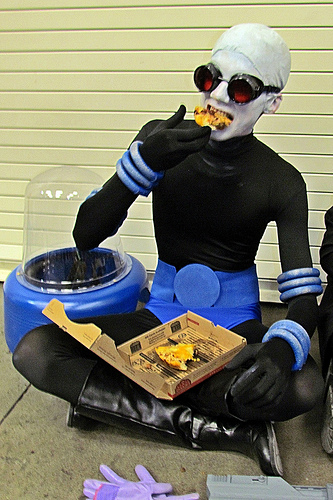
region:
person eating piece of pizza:
[57, 19, 304, 300]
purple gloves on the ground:
[88, 459, 183, 498]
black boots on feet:
[67, 394, 278, 475]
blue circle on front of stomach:
[167, 261, 220, 316]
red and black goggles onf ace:
[193, 56, 267, 100]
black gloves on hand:
[223, 344, 295, 408]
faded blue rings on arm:
[247, 268, 320, 361]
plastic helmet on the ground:
[17, 160, 125, 293]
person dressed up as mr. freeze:
[46, 29, 321, 332]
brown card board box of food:
[99, 315, 236, 392]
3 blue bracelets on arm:
[275, 267, 330, 298]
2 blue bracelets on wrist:
[265, 312, 315, 368]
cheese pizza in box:
[154, 342, 200, 375]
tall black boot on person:
[102, 410, 283, 472]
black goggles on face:
[193, 65, 266, 105]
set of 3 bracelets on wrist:
[114, 142, 160, 197]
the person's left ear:
[262, 92, 287, 115]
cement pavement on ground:
[0, 419, 56, 496]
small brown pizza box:
[40, 296, 248, 401]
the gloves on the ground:
[71, 441, 188, 499]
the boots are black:
[47, 345, 292, 467]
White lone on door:
[10, 6, 78, 17]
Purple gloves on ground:
[70, 455, 183, 499]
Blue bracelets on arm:
[262, 264, 329, 297]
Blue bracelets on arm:
[258, 315, 313, 381]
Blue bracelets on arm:
[95, 139, 163, 199]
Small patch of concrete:
[1, 462, 36, 499]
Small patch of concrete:
[36, 455, 59, 499]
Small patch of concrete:
[56, 452, 86, 494]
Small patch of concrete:
[80, 430, 125, 478]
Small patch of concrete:
[120, 436, 176, 478]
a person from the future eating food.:
[186, 97, 244, 145]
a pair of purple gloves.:
[73, 437, 188, 495]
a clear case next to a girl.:
[2, 131, 162, 349]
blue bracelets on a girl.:
[111, 136, 166, 202]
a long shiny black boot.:
[61, 361, 287, 479]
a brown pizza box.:
[41, 290, 267, 412]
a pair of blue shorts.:
[139, 254, 279, 359]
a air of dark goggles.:
[183, 53, 291, 111]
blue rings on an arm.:
[250, 312, 321, 377]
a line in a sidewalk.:
[0, 370, 38, 423]